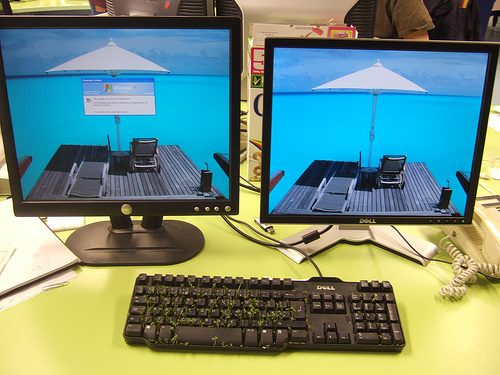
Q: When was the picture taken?
A: Daytime.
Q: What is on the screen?
A: A picture.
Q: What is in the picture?
A: An umbrella and the ocean.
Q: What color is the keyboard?
A: Black.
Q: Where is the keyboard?
A: On the desk.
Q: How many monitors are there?
A: Two.